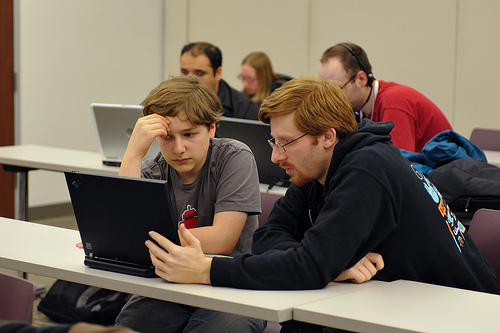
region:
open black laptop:
[44, 170, 174, 242]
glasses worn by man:
[264, 139, 296, 160]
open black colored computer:
[58, 168, 175, 232]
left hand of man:
[131, 219, 206, 280]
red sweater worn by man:
[381, 80, 449, 145]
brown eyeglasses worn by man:
[255, 123, 305, 155]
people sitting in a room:
[57, 35, 493, 331]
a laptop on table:
[58, 160, 196, 277]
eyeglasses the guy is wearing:
[264, 128, 314, 158]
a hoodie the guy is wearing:
[203, 120, 499, 298]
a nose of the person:
[170, 135, 186, 155]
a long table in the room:
[1, 215, 498, 331]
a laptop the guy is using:
[89, 102, 164, 167]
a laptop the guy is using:
[218, 113, 287, 185]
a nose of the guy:
[268, 138, 288, 165]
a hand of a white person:
[141, 220, 211, 286]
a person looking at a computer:
[104, 84, 255, 266]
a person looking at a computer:
[248, 95, 451, 326]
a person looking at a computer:
[180, 38, 243, 148]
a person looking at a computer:
[303, 28, 468, 213]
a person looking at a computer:
[222, 33, 300, 138]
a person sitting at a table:
[111, 73, 291, 331]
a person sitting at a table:
[257, 70, 390, 252]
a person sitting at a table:
[155, 28, 238, 142]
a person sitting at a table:
[323, 40, 431, 163]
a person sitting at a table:
[228, 33, 318, 131]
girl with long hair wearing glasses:
[237, 49, 292, 104]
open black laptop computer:
[59, 160, 238, 279]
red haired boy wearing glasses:
[143, 76, 495, 290]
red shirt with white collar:
[369, 72, 451, 153]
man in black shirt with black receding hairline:
[178, 39, 258, 119]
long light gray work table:
[1, 210, 498, 327]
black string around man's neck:
[351, 80, 375, 110]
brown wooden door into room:
[0, 2, 17, 221]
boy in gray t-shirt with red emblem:
[114, 74, 263, 331]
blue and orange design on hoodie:
[401, 156, 472, 259]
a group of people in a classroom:
[117, 40, 496, 331]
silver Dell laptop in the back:
[90, 100, 166, 167]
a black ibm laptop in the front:
[61, 164, 186, 276]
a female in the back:
[235, 52, 283, 105]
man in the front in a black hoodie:
[144, 75, 498, 295]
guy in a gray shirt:
[108, 78, 265, 331]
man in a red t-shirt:
[318, 41, 451, 154]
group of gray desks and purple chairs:
[0, 128, 498, 331]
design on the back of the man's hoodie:
[409, 163, 466, 251]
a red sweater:
[376, 75, 465, 160]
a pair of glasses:
[325, 73, 359, 88]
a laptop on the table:
[50, 163, 200, 268]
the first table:
[2, 211, 498, 329]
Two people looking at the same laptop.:
[65, 80, 462, 300]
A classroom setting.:
[22, 29, 497, 319]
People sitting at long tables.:
[10, 50, 499, 322]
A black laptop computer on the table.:
[63, 170, 202, 289]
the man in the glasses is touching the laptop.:
[158, 74, 456, 289]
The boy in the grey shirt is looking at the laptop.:
[72, 73, 260, 278]